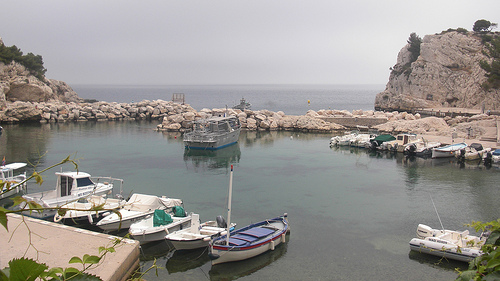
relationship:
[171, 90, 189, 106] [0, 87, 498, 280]
stand in harbor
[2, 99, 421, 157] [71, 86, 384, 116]
rocks near ocean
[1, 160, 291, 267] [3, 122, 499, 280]
boats on water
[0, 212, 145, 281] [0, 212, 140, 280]
platform of building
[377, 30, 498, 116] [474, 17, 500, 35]
cliff has tree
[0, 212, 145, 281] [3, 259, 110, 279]
platform has ivy